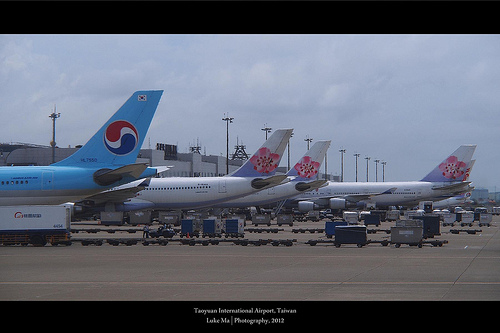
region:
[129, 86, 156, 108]
South korean flag on top of the tail of the aircraft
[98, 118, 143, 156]
Airline logo on the tail of the airfcraft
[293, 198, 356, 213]
Engine on the aircraft under the wings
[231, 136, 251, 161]
Antenna on the airport on the roof of the terminal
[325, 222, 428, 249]
Luggage boxes behind the aircraft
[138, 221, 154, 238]
Aircraft mechanic crew near the lugagge tow vehicle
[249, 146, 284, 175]
Pink flower logo on the tail of the aircraft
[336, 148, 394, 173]
Terminal gate lights on the airport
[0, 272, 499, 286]
Taxi way line on the airport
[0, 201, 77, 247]
White truck on the airport next to the aircraft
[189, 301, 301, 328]
white on black text describing the photo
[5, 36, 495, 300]
several jet airplanes being serviced at their gates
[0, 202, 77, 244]
white service vehicle for an airline on gray tarmac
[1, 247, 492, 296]
gray pavement of a tarmac at an airport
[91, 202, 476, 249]
service vehicles on the tarmac at an airport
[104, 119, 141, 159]
red, white and blue logo on a jet airliner's tail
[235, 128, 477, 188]
tails of five jet airplanes with pink flowers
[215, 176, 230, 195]
rear emergency exit door of a jet airplane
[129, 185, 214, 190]
windows along the seating section of a jet airplane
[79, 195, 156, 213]
blue painted engine on the left wing of a jet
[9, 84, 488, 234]
planes at a terminal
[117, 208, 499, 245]
luggage carts at a terminal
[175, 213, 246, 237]
three luggage carts in a row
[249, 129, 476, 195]
planes with flowers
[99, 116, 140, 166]
a red white and blue swirl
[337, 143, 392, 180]
light poles in a row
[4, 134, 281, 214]
an airport terminal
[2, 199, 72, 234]
a truck near the plane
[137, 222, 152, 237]
a person at an airport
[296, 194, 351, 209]
engines on a plane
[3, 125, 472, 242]
many planes parked at a terminal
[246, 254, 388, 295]
black concrete surface of the tarmac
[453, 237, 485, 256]
white lines painted on the ground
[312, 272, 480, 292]
yellow line painted on the ground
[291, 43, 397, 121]
cloudy white skies over the airport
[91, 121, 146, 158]
red, white and blue logo on the tail fin of the blue plane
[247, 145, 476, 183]
pink flower on the tail fins of the white planes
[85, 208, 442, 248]
several carts of luggage next to the planes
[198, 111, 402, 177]
several wind turbines next to the terminal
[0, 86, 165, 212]
a blue plane parked at the terminal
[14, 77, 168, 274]
plane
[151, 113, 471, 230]
airplanes in airport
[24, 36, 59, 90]
white clouds in blue sky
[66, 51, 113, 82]
white clouds in blue sky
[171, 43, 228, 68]
white clouds in blue sky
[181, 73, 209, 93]
white clouds in blue sky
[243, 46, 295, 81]
white clouds in blue sky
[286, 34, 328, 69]
white clouds in blue sky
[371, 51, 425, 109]
white clouds in blue sky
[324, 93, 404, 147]
white clouds in blue sky